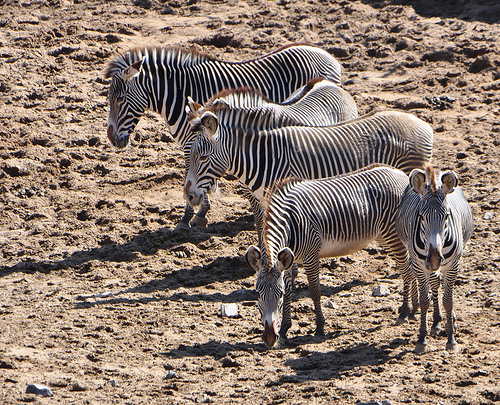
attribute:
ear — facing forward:
[243, 243, 262, 273]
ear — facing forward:
[274, 243, 294, 272]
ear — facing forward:
[407, 166, 428, 195]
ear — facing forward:
[437, 167, 459, 196]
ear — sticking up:
[242, 240, 262, 269]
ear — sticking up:
[272, 244, 296, 273]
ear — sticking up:
[404, 164, 427, 194]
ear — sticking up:
[435, 166, 459, 194]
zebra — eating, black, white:
[243, 160, 421, 348]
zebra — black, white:
[100, 40, 349, 230]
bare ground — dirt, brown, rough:
[1, 2, 499, 403]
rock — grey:
[220, 300, 242, 320]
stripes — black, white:
[112, 50, 343, 174]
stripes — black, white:
[187, 113, 414, 171]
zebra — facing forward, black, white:
[397, 165, 476, 357]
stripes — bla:
[411, 186, 461, 314]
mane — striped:
[104, 44, 213, 80]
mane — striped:
[260, 173, 302, 269]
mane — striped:
[424, 168, 439, 193]